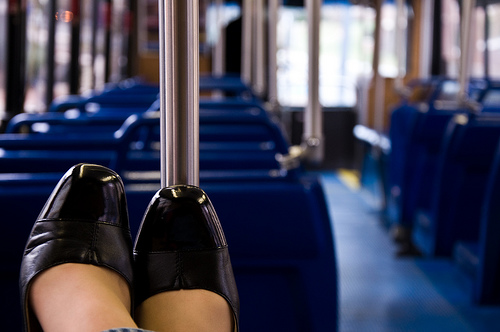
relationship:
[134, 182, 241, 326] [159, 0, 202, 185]
foot leaning on pole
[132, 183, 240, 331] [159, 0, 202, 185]
shoe leaning on pole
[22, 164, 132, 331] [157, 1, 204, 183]
black pumps leaning on pole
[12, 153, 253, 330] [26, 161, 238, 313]
woman wearing black pumps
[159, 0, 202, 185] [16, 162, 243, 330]
pole in front of woman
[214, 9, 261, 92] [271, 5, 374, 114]
person standing by window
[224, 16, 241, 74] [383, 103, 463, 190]
person sitting in seat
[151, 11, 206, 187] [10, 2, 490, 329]
pole on a bus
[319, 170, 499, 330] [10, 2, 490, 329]
walkway on a bus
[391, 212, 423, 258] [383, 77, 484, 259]
legs of a seat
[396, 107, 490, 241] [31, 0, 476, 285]
seat on a bus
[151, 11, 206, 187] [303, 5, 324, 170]
pole on a pole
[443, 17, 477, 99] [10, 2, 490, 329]
pole on a bus